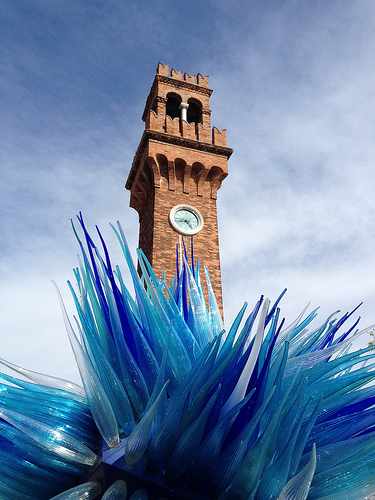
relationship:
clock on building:
[167, 203, 205, 237] [123, 60, 233, 328]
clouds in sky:
[0, 0, 375, 387] [0, 0, 375, 389]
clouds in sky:
[0, 0, 375, 387] [0, 1, 375, 394]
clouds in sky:
[0, 0, 375, 387] [6, 1, 373, 58]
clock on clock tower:
[154, 196, 194, 241] [123, 58, 235, 330]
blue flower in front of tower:
[38, 244, 329, 432] [107, 50, 267, 376]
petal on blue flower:
[107, 217, 143, 301] [0, 206, 375, 500]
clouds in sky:
[0, 0, 375, 387] [4, 2, 373, 349]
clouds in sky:
[281, 81, 369, 167] [288, 45, 368, 146]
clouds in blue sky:
[0, 0, 375, 387] [35, 37, 117, 85]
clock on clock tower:
[167, 203, 205, 237] [123, 58, 235, 330]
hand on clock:
[185, 219, 194, 230] [151, 194, 210, 253]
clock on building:
[167, 203, 205, 237] [156, 198, 201, 240]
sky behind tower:
[265, 33, 346, 144] [124, 26, 269, 239]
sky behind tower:
[265, 33, 346, 144] [110, 61, 250, 305]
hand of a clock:
[174, 212, 189, 222] [162, 193, 205, 240]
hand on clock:
[185, 219, 194, 230] [167, 203, 205, 237]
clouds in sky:
[0, 0, 375, 387] [194, 0, 374, 325]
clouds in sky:
[0, 0, 375, 387] [36, 28, 127, 103]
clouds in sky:
[0, 0, 375, 387] [18, 17, 110, 136]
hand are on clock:
[185, 219, 194, 230] [167, 203, 205, 237]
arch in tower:
[160, 87, 188, 112] [119, 49, 237, 355]